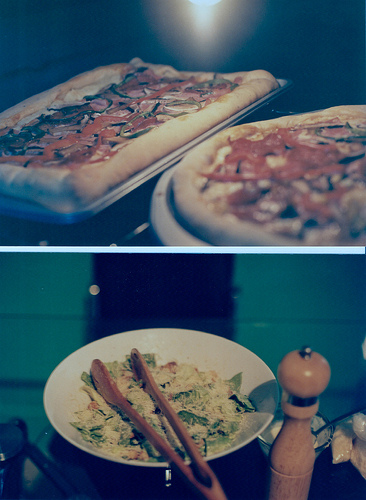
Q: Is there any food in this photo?
A: Yes, there is food.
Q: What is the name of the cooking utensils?
A: The cooking utensils are tongs.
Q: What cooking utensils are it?
A: The cooking utensils are tongs.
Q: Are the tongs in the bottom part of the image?
A: Yes, the tongs are in the bottom of the image.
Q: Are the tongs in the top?
A: No, the tongs are in the bottom of the image.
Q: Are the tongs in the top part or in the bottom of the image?
A: The tongs are in the bottom of the image.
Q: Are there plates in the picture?
A: Yes, there is a plate.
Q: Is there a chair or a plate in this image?
A: Yes, there is a plate.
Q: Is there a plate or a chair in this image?
A: Yes, there is a plate.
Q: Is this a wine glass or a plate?
A: This is a plate.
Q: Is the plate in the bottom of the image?
A: Yes, the plate is in the bottom of the image.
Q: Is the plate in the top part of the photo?
A: No, the plate is in the bottom of the image.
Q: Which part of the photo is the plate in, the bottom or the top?
A: The plate is in the bottom of the image.